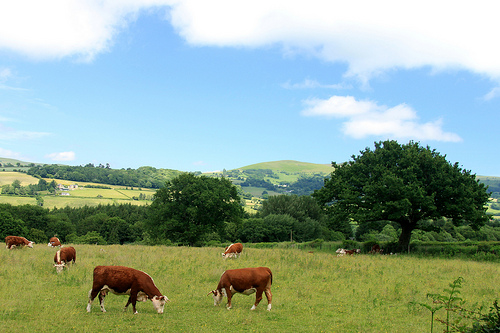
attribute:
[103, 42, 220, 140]
skies — blue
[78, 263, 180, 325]
cow — brown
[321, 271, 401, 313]
grass — green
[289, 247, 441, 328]
grass — light green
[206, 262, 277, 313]
cow — brown, white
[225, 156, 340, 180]
hill — in the background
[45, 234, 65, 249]
cow — brown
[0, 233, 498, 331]
grass — green, on ground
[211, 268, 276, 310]
cows — grazing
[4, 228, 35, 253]
brown cow — Grazing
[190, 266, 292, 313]
cow — brown, grazing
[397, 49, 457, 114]
clouds — white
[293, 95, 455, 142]
clouds — white 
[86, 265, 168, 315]
cow — brown , white 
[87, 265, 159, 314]
cow — brown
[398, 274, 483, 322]
weeds/field — Green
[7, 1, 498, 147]
clouds — white